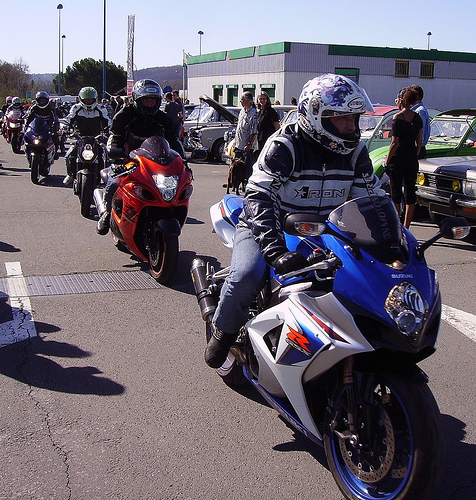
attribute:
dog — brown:
[224, 157, 252, 191]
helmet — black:
[135, 80, 160, 113]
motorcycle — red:
[100, 126, 193, 279]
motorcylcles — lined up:
[4, 77, 442, 485]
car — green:
[373, 105, 475, 200]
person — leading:
[203, 76, 405, 388]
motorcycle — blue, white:
[197, 183, 441, 484]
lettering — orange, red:
[290, 322, 314, 351]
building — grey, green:
[190, 37, 475, 124]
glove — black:
[275, 240, 307, 269]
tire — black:
[316, 358, 458, 498]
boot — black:
[204, 331, 237, 367]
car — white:
[187, 94, 302, 145]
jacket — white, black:
[242, 133, 396, 261]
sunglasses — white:
[393, 98, 401, 105]